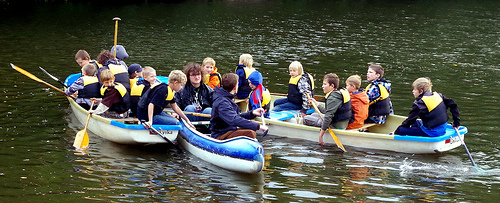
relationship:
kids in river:
[63, 43, 424, 132] [0, 0, 499, 203]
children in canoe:
[87, 53, 157, 116] [54, 61, 170, 147]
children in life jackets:
[87, 53, 157, 116] [85, 65, 142, 106]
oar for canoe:
[69, 126, 106, 154] [54, 61, 170, 147]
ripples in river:
[278, 152, 313, 196] [0, 0, 499, 203]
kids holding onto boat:
[63, 43, 424, 132] [146, 76, 266, 174]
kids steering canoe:
[63, 43, 424, 132] [54, 61, 170, 147]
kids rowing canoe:
[63, 43, 424, 132] [54, 61, 170, 147]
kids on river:
[63, 43, 424, 132] [6, 10, 496, 200]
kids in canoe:
[63, 43, 424, 132] [54, 61, 170, 147]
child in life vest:
[342, 70, 371, 136] [354, 91, 370, 127]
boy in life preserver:
[390, 77, 461, 137] [417, 91, 450, 128]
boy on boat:
[390, 77, 461, 137] [200, 64, 463, 156]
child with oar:
[91, 70, 126, 127] [69, 126, 106, 154]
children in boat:
[87, 53, 157, 116] [200, 64, 463, 156]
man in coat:
[207, 71, 270, 141] [205, 87, 260, 138]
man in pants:
[207, 71, 270, 141] [208, 123, 252, 141]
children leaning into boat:
[135, 69, 200, 130] [174, 67, 252, 172]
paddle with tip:
[67, 97, 103, 163] [73, 125, 92, 150]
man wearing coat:
[207, 71, 270, 141] [205, 87, 260, 138]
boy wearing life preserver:
[390, 77, 461, 137] [417, 91, 437, 117]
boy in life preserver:
[411, 78, 441, 129] [417, 91, 450, 128]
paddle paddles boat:
[67, 97, 103, 163] [200, 64, 463, 156]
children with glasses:
[135, 69, 200, 130] [188, 71, 206, 80]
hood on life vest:
[355, 84, 366, 103] [344, 91, 370, 128]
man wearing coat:
[207, 65, 244, 132] [215, 92, 242, 125]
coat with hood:
[215, 92, 242, 125] [204, 82, 218, 104]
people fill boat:
[80, 37, 442, 131] [200, 64, 463, 156]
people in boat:
[80, 37, 442, 131] [200, 64, 463, 156]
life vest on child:
[354, 91, 370, 127] [342, 74, 370, 129]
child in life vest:
[342, 74, 370, 129] [344, 91, 370, 128]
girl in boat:
[187, 61, 212, 121] [200, 64, 463, 156]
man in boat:
[207, 71, 270, 141] [200, 64, 463, 156]